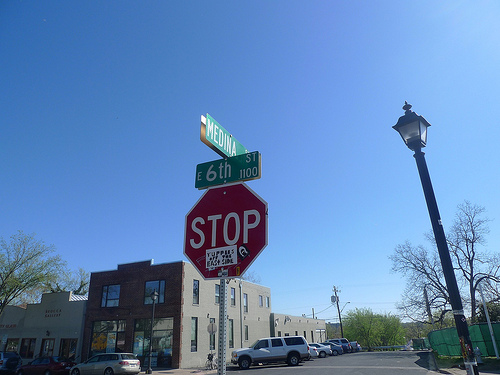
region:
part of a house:
[256, 301, 261, 309]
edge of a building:
[248, 293, 256, 307]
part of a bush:
[397, 332, 404, 342]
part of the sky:
[395, 230, 400, 240]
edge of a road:
[366, 323, 371, 340]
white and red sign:
[188, 181, 272, 288]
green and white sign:
[188, 145, 269, 189]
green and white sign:
[194, 102, 251, 154]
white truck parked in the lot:
[234, 326, 315, 370]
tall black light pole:
[384, 93, 496, 371]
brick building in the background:
[90, 263, 328, 371]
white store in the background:
[2, 281, 83, 373]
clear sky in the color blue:
[11, 0, 496, 261]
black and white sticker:
[199, 243, 237, 267]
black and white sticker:
[234, 246, 247, 256]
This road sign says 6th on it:
[196, 158, 238, 207]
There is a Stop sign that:
[196, 187, 273, 354]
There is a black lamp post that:
[417, 170, 445, 237]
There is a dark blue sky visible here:
[306, 165, 321, 198]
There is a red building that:
[125, 259, 169, 366]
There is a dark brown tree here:
[406, 243, 423, 276]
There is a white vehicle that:
[258, 339, 271, 366]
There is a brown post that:
[336, 310, 353, 335]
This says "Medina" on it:
[195, 110, 236, 174]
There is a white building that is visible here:
[50, 305, 62, 327]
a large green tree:
[339, 308, 384, 350]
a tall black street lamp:
[390, 103, 481, 368]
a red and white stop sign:
[183, 185, 268, 282]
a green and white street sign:
[190, 149, 264, 185]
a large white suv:
[227, 335, 311, 370]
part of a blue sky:
[31, 46, 189, 141]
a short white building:
[0, 288, 89, 371]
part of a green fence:
[426, 323, 493, 357]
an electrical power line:
[302, 300, 332, 319]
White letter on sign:
[188, 213, 205, 252]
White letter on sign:
[202, 212, 221, 247]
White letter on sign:
[223, 208, 242, 246]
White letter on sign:
[243, 207, 262, 247]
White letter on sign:
[216, 160, 223, 177]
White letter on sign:
[222, 158, 230, 178]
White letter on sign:
[204, 118, 217, 139]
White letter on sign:
[211, 122, 221, 144]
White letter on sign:
[218, 127, 225, 153]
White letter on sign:
[221, 130, 234, 157]